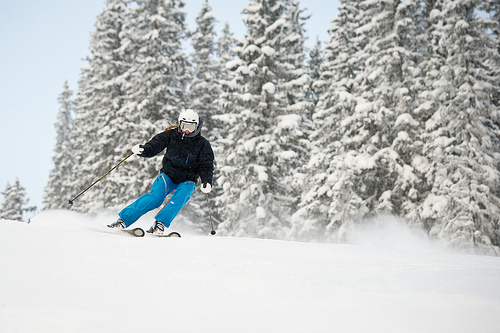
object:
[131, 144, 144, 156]
hand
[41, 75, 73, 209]
pine tree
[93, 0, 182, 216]
pine tree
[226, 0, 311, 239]
pine tree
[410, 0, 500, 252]
pine tree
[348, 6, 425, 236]
pine tree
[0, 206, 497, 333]
hill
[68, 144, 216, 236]
black poles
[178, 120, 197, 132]
eyeprotector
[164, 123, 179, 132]
hair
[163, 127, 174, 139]
shoulder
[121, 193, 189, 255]
skiing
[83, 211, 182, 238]
skis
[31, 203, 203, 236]
puff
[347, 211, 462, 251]
puff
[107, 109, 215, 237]
lady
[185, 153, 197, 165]
line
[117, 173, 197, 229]
pants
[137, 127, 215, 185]
jacket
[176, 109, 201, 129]
helmet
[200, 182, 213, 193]
gloves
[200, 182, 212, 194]
skiers hands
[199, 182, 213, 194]
hands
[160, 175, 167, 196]
zipper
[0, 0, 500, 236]
snow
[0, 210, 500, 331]
ground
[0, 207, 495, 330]
snow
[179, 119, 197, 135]
face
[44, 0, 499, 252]
trees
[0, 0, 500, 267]
background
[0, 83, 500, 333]
game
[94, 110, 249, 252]
skatting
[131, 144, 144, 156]
gloves